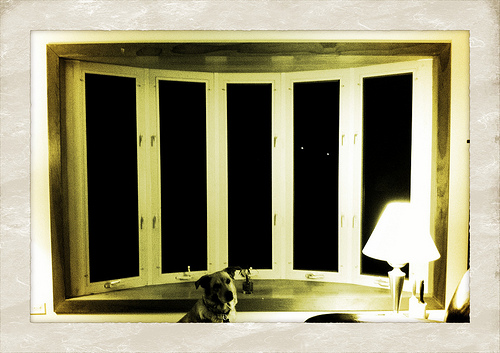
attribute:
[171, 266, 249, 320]
dog — black, white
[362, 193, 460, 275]
shade — yellow, lamp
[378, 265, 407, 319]
lamp — metal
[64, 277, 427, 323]
ledge — gray, window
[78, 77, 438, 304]
windows — closed